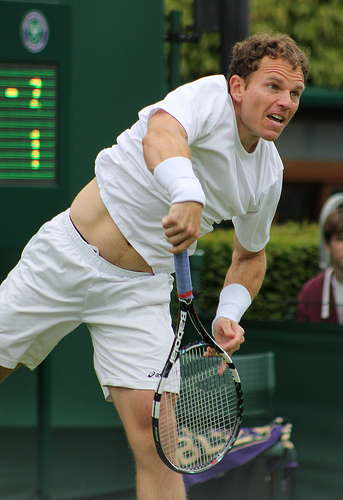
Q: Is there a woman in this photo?
A: No, there are no women.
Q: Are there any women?
A: No, there are no women.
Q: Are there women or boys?
A: No, there are no women or boys.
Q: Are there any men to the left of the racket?
A: No, the man is to the right of the racket.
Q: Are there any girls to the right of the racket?
A: No, there is a man to the right of the racket.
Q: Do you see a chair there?
A: Yes, there is a chair.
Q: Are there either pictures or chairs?
A: Yes, there is a chair.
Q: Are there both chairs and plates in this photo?
A: No, there is a chair but no plates.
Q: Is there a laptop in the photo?
A: No, there are no laptops.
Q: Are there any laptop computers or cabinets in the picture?
A: No, there are no laptop computers or cabinets.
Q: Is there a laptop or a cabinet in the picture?
A: No, there are no laptops or cabinets.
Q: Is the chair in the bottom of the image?
A: Yes, the chair is in the bottom of the image.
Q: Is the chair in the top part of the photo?
A: No, the chair is in the bottom of the image.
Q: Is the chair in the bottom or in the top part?
A: The chair is in the bottom of the image.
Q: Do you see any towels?
A: Yes, there is a towel.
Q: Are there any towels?
A: Yes, there is a towel.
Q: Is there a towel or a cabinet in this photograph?
A: Yes, there is a towel.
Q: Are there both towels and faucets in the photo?
A: No, there is a towel but no faucets.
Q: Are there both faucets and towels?
A: No, there is a towel but no faucets.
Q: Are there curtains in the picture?
A: No, there are no curtains.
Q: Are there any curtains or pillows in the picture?
A: No, there are no curtains or pillows.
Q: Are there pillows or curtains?
A: No, there are no curtains or pillows.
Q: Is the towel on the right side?
A: Yes, the towel is on the right of the image.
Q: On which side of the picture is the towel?
A: The towel is on the right of the image.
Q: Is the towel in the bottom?
A: Yes, the towel is in the bottom of the image.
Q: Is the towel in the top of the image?
A: No, the towel is in the bottom of the image.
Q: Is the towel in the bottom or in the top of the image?
A: The towel is in the bottom of the image.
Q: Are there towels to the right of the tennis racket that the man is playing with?
A: Yes, there is a towel to the right of the racket.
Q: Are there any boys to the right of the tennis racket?
A: No, there is a towel to the right of the tennis racket.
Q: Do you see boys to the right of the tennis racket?
A: No, there is a towel to the right of the tennis racket.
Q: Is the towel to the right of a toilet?
A: No, the towel is to the right of a racket.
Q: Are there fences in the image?
A: No, there are no fences.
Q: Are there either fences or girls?
A: No, there are no fences or girls.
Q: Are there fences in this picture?
A: No, there are no fences.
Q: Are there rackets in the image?
A: Yes, there is a racket.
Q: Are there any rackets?
A: Yes, there is a racket.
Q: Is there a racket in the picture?
A: Yes, there is a racket.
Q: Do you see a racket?
A: Yes, there is a racket.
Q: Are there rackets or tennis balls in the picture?
A: Yes, there is a racket.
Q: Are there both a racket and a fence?
A: No, there is a racket but no fences.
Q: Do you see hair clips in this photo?
A: No, there are no hair clips.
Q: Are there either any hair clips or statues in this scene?
A: No, there are no hair clips or statues.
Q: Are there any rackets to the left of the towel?
A: Yes, there is a racket to the left of the towel.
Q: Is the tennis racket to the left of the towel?
A: Yes, the tennis racket is to the left of the towel.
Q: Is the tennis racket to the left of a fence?
A: No, the tennis racket is to the left of the towel.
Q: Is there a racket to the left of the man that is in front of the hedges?
A: Yes, there is a racket to the left of the man.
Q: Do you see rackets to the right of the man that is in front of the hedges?
A: No, the racket is to the left of the man.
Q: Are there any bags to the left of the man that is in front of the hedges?
A: No, there is a racket to the left of the man.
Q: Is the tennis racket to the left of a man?
A: Yes, the tennis racket is to the left of a man.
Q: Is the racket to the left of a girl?
A: No, the racket is to the left of a man.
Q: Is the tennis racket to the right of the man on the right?
A: No, the tennis racket is to the left of the man.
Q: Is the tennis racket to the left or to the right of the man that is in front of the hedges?
A: The tennis racket is to the left of the man.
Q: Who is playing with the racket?
A: The man is playing with the racket.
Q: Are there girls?
A: No, there are no girls.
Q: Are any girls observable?
A: No, there are no girls.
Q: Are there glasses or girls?
A: No, there are no girls or glasses.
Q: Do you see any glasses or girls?
A: No, there are no girls or glasses.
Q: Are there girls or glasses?
A: No, there are no girls or glasses.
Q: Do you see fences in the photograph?
A: No, there are no fences.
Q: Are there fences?
A: No, there are no fences.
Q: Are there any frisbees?
A: No, there are no frisbees.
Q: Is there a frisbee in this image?
A: No, there are no frisbees.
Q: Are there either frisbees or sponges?
A: No, there are no frisbees or sponges.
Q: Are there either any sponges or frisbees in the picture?
A: No, there are no frisbees or sponges.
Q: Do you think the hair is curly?
A: Yes, the hair is curly.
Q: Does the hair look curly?
A: Yes, the hair is curly.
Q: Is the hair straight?
A: No, the hair is curly.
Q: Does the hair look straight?
A: No, the hair is curly.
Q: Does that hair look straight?
A: No, the hair is curly.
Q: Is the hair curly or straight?
A: The hair is curly.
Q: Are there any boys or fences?
A: No, there are no boys or fences.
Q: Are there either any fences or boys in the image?
A: No, there are no boys or fences.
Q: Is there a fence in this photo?
A: No, there are no fences.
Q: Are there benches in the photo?
A: No, there are no benches.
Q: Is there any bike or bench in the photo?
A: No, there are no benches or bikes.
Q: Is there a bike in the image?
A: No, there are no bikes.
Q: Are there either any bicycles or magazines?
A: No, there are no bicycles or magazines.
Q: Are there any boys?
A: No, there are no boys.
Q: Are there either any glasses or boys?
A: No, there are no boys or glasses.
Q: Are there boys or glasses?
A: No, there are no boys or glasses.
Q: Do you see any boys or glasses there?
A: No, there are no boys or glasses.